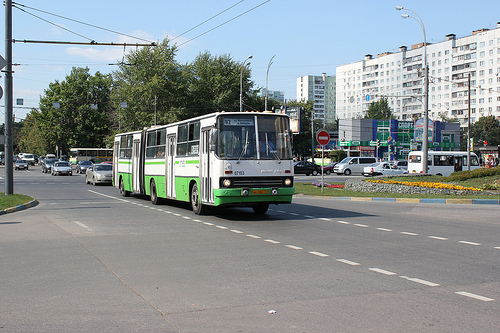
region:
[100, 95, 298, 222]
a green and white bus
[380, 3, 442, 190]
a very tall lamp post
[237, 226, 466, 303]
lines indicating traffic flow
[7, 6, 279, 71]
several power lines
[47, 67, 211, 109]
tall leafy trees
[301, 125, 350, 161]
a round stop sign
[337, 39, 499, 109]
a very large tenement building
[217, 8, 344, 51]
a clear blue sky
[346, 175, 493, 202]
well manicured garden flowers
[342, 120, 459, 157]
a store with a blue and green facad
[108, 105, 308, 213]
green and white city bus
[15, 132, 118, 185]
cars travelling on the street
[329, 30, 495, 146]
high rise apartment building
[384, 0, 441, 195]
two street lights on silver pole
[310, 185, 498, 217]
blue and yellow street curb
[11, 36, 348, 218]
tree lined street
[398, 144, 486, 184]
white shuttle van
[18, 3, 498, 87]
blue sky with a few clouds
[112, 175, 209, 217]
three tires on a bus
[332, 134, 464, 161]
green street signs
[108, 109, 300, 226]
bus on the street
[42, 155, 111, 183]
cars are near bus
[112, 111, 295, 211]
bus is green and white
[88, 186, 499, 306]
street has white stripes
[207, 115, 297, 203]
bus has lights on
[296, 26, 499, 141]
buildings are behind bus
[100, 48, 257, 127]
trees are behind the bus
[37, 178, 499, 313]
street is gray with stripes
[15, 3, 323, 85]
sky has small clouds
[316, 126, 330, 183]
sign is red and white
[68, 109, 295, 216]
two buses are driving on the street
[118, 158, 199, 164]
bus has green stripes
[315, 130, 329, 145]
do not enter sign next to bus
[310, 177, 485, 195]
flowers next to bus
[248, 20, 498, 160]
buildings are behind the cars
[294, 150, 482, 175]
cars are parked in a parking lot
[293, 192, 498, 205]
yellow and blue curb next to bus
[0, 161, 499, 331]
street is busy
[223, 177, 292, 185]
two headlights on front of bus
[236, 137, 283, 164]
windshield wipers on front of bus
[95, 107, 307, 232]
the bus is green and white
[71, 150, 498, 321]
the road has white lines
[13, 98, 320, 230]
cars are behind the bus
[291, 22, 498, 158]
the building is white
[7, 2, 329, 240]
power lines above the bus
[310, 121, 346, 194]
a stop sign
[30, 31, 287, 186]
the trees are green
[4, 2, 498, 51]
the sky is blue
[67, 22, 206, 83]
a white cloud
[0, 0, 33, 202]
a gray pole